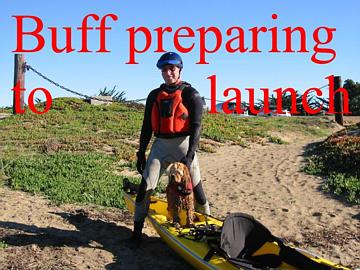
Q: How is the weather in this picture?
A: It is clear.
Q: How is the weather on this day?
A: It is clear.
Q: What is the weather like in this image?
A: It is clear.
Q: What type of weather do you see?
A: It is clear.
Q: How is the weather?
A: It is clear.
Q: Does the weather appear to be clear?
A: Yes, it is clear.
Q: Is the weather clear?
A: Yes, it is clear.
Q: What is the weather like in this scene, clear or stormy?
A: It is clear.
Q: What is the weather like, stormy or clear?
A: It is clear.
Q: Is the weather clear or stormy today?
A: It is clear.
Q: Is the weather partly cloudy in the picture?
A: No, it is clear.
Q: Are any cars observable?
A: No, there are no cars.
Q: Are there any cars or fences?
A: No, there are no cars or fences.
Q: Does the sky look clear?
A: Yes, the sky is clear.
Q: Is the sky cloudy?
A: No, the sky is clear.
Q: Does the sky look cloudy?
A: No, the sky is clear.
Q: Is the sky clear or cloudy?
A: The sky is clear.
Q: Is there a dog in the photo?
A: Yes, there is a dog.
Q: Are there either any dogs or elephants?
A: Yes, there is a dog.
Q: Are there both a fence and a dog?
A: No, there is a dog but no fences.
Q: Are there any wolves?
A: No, there are no wolves.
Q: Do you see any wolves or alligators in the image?
A: No, there are no wolves or alligators.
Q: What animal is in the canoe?
A: The animal is a dog.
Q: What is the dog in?
A: The dog is in the kayak.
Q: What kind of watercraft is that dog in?
A: The dog is in the kayak.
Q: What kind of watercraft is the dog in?
A: The dog is in the kayak.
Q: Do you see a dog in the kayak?
A: Yes, there is a dog in the kayak.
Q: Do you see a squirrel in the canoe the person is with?
A: No, there is a dog in the canoe.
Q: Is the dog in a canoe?
A: Yes, the dog is in a canoe.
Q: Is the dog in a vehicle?
A: No, the dog is in a canoe.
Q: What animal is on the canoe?
A: The dog is on the canoe.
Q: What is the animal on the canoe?
A: The animal is a dog.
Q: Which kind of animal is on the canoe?
A: The animal is a dog.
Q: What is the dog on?
A: The dog is on the kayak.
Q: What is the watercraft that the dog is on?
A: The watercraft is a canoe.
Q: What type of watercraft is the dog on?
A: The dog is on the canoe.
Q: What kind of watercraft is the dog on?
A: The dog is on the canoe.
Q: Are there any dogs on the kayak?
A: Yes, there is a dog on the kayak.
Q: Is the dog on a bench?
A: No, the dog is on the canoe.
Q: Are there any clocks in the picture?
A: No, there are no clocks.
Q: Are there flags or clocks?
A: No, there are no clocks or flags.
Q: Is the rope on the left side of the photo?
A: Yes, the rope is on the left of the image.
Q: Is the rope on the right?
A: No, the rope is on the left of the image.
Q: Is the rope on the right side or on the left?
A: The rope is on the left of the image.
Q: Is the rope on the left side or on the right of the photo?
A: The rope is on the left of the image.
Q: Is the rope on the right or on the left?
A: The rope is on the left of the image.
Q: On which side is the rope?
A: The rope is on the left of the image.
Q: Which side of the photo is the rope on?
A: The rope is on the left of the image.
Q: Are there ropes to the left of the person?
A: Yes, there is a rope to the left of the person.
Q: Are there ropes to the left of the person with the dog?
A: Yes, there is a rope to the left of the person.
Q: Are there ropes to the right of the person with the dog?
A: No, the rope is to the left of the person.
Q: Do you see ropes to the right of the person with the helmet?
A: No, the rope is to the left of the person.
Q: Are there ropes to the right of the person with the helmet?
A: No, the rope is to the left of the person.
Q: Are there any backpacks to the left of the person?
A: No, there is a rope to the left of the person.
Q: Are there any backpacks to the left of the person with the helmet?
A: No, there is a rope to the left of the person.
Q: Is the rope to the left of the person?
A: Yes, the rope is to the left of the person.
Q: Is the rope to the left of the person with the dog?
A: Yes, the rope is to the left of the person.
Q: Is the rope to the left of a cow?
A: No, the rope is to the left of the person.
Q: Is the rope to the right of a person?
A: No, the rope is to the left of a person.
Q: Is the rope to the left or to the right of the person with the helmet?
A: The rope is to the left of the person.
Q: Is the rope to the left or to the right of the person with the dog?
A: The rope is to the left of the person.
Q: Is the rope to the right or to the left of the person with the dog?
A: The rope is to the left of the person.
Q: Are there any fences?
A: No, there are no fences.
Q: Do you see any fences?
A: No, there are no fences.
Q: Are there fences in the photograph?
A: No, there are no fences.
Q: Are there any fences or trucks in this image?
A: No, there are no fences or trucks.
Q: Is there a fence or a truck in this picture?
A: No, there are no fences or trucks.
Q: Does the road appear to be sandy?
A: Yes, the road is sandy.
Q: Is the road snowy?
A: No, the road is sandy.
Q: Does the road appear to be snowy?
A: No, the road is sandy.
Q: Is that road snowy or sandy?
A: The road is sandy.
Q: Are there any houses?
A: No, there are no houses.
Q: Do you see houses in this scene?
A: No, there are no houses.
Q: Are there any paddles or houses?
A: No, there are no houses or paddles.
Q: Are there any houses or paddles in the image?
A: No, there are no houses or paddles.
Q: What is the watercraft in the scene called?
A: The watercraft is a canoe.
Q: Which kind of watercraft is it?
A: The watercraft is a canoe.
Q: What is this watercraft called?
A: This is a canoe.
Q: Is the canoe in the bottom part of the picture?
A: Yes, the canoe is in the bottom of the image.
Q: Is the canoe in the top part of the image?
A: No, the canoe is in the bottom of the image.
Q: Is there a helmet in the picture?
A: Yes, there is a helmet.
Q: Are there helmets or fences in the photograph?
A: Yes, there is a helmet.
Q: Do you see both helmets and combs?
A: No, there is a helmet but no combs.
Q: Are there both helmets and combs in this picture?
A: No, there is a helmet but no combs.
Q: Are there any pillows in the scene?
A: No, there are no pillows.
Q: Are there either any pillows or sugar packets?
A: No, there are no pillows or sugar packets.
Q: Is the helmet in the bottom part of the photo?
A: No, the helmet is in the top of the image.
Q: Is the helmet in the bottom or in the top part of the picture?
A: The helmet is in the top of the image.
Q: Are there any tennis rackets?
A: No, there are no tennis rackets.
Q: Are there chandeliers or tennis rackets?
A: No, there are no tennis rackets or chandeliers.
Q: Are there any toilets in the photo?
A: No, there are no toilets.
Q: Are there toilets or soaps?
A: No, there are no toilets or soaps.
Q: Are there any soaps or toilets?
A: No, there are no toilets or soaps.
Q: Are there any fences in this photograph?
A: No, there are no fences.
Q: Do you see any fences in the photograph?
A: No, there are no fences.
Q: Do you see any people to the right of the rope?
A: Yes, there is a person to the right of the rope.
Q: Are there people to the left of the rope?
A: No, the person is to the right of the rope.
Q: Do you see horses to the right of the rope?
A: No, there is a person to the right of the rope.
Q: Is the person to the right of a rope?
A: Yes, the person is to the right of a rope.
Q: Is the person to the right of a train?
A: No, the person is to the right of a rope.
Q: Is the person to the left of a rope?
A: No, the person is to the right of a rope.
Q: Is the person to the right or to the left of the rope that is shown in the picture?
A: The person is to the right of the rope.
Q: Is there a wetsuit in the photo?
A: Yes, there is a wetsuit.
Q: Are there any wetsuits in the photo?
A: Yes, there is a wetsuit.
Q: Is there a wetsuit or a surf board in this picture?
A: Yes, there is a wetsuit.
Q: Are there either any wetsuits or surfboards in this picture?
A: Yes, there is a wetsuit.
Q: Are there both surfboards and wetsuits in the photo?
A: No, there is a wetsuit but no surfboards.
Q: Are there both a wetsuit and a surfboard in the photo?
A: No, there is a wetsuit but no surfboards.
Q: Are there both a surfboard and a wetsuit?
A: No, there is a wetsuit but no surfboards.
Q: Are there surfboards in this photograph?
A: No, there are no surfboards.